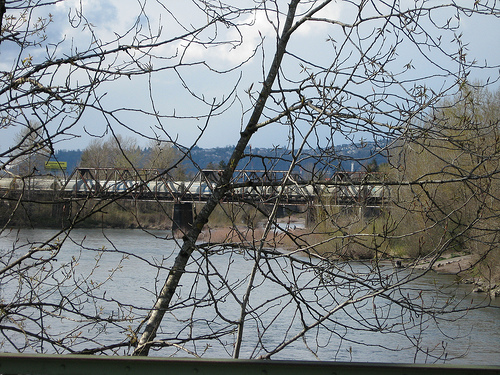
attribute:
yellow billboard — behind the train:
[43, 160, 68, 169]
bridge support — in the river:
[168, 201, 197, 231]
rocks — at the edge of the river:
[457, 265, 478, 290]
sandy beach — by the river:
[407, 249, 467, 276]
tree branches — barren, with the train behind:
[6, 4, 371, 344]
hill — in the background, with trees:
[1, 145, 377, 177]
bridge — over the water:
[1, 187, 396, 209]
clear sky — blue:
[30, 86, 195, 143]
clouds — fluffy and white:
[64, 1, 310, 76]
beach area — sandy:
[391, 251, 498, 293]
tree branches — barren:
[3, 0, 497, 363]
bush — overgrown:
[216, 79, 496, 268]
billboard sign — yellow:
[41, 160, 67, 170]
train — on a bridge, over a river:
[2, 175, 409, 203]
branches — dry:
[255, 237, 418, 329]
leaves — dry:
[296, 30, 462, 152]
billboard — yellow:
[38, 158, 69, 170]